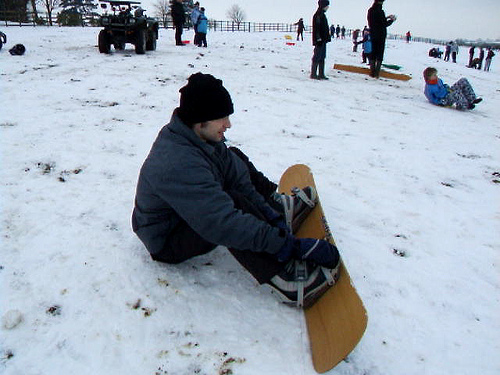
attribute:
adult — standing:
[164, 0, 200, 57]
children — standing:
[192, 5, 212, 53]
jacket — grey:
[127, 107, 292, 259]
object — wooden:
[333, 62, 410, 81]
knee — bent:
[228, 139, 246, 166]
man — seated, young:
[151, 73, 336, 345]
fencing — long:
[9, 5, 351, 40]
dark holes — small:
[435, 176, 470, 204]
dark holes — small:
[390, 245, 408, 265]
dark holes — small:
[132, 293, 149, 315]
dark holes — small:
[48, 301, 64, 319]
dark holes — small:
[38, 160, 54, 179]